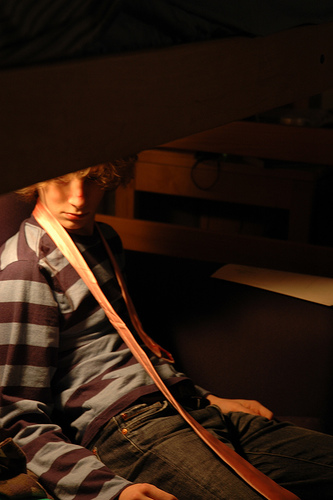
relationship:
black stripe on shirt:
[0, 301, 59, 332] [2, 217, 208, 499]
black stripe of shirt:
[11, 243, 42, 300] [2, 217, 208, 499]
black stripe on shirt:
[0, 342, 53, 368] [2, 217, 208, 499]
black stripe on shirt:
[51, 262, 80, 294] [0, 227, 156, 421]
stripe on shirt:
[26, 214, 44, 229] [2, 217, 208, 499]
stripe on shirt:
[17, 220, 37, 262] [2, 217, 208, 499]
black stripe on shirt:
[0, 263, 52, 286] [2, 217, 208, 499]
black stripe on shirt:
[51, 262, 80, 294] [2, 217, 208, 499]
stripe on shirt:
[16, 431, 74, 463] [6, 200, 212, 431]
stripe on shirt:
[38, 445, 92, 490] [2, 217, 208, 499]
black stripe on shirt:
[0, 301, 59, 332] [0, 221, 184, 419]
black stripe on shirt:
[0, 264, 36, 277] [1, 215, 186, 496]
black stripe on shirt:
[0, 301, 59, 332] [1, 215, 186, 496]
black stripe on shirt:
[3, 348, 48, 361] [1, 215, 186, 496]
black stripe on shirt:
[60, 271, 73, 281] [1, 215, 186, 496]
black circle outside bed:
[188, 153, 221, 191] [66, 90, 315, 343]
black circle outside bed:
[188, 153, 221, 191] [2, 2, 331, 293]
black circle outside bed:
[188, 153, 221, 191] [94, 87, 331, 272]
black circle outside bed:
[188, 153, 221, 191] [141, 215, 318, 361]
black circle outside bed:
[188, 153, 221, 191] [187, 154, 271, 251]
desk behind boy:
[124, 119, 328, 270] [0, 155, 333, 499]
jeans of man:
[142, 429, 215, 496] [30, 166, 187, 379]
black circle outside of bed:
[188, 153, 221, 191] [18, 199, 246, 305]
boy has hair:
[0, 155, 333, 499] [5, 161, 113, 203]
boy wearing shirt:
[2, 154, 331, 497] [2, 217, 208, 499]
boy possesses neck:
[2, 154, 331, 497] [32, 205, 101, 237]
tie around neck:
[30, 199, 298, 499] [32, 205, 101, 237]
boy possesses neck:
[0, 155, 333, 499] [32, 201, 98, 234]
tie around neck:
[30, 199, 177, 363] [32, 201, 98, 234]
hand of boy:
[206, 392, 273, 419] [2, 154, 331, 497]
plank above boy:
[0, 31, 332, 194] [0, 155, 333, 499]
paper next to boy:
[209, 254, 328, 333] [30, 207, 246, 472]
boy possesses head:
[0, 155, 333, 499] [33, 135, 123, 228]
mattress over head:
[123, 175, 326, 338] [33, 135, 123, 228]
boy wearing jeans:
[2, 154, 331, 497] [91, 395, 331, 498]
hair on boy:
[91, 160, 136, 196] [20, 170, 272, 480]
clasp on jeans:
[117, 425, 129, 437] [86, 377, 331, 498]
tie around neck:
[30, 199, 298, 499] [22, 192, 122, 254]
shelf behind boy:
[90, 142, 330, 276] [2, 154, 331, 497]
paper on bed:
[210, 261, 332, 309] [247, 304, 270, 330]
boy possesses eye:
[0, 155, 333, 499] [82, 178, 98, 186]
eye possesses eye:
[82, 178, 98, 186] [54, 179, 69, 189]